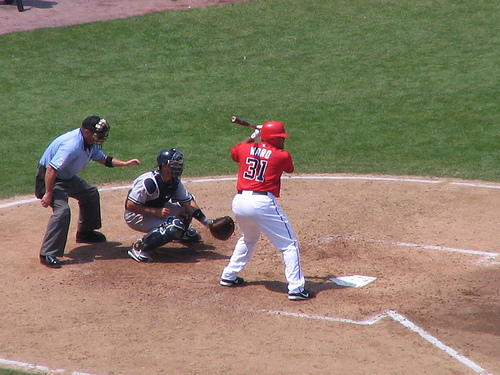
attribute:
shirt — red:
[227, 139, 293, 196]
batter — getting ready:
[219, 119, 316, 304]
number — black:
[245, 158, 267, 182]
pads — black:
[146, 176, 175, 201]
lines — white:
[349, 305, 457, 370]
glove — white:
[250, 123, 262, 138]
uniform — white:
[213, 188, 305, 303]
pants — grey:
[32, 166, 106, 256]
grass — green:
[1, 2, 498, 212]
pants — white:
[219, 190, 307, 292]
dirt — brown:
[1, 172, 498, 372]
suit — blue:
[32, 126, 110, 274]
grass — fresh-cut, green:
[1, 60, 473, 182]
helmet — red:
[255, 118, 290, 140]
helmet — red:
[248, 125, 294, 150]